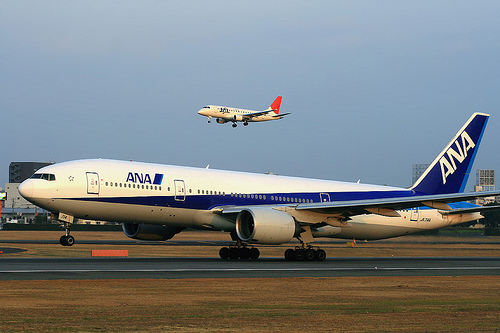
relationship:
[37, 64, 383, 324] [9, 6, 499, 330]
planes at an airport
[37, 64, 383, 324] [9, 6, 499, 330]
two planes at an airport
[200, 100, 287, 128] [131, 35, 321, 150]
plane in air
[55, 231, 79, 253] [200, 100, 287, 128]
front tires on plane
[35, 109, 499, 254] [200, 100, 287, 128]
white and blue plane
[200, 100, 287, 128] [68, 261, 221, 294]
plane on runway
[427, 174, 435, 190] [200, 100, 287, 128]
blue and white plane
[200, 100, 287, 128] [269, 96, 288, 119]
plane has orange tail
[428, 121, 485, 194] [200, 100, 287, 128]
ana on plane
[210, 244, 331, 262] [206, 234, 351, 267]
black plane tires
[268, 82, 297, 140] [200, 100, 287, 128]
red tail end of plane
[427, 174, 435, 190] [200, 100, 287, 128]
blue end of plane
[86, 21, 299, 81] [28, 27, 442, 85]
clear blue sky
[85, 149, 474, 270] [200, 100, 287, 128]
right side of plane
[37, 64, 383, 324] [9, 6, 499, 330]
planes are in airport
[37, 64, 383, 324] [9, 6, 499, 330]
planes in an airport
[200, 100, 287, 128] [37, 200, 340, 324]
plane taking off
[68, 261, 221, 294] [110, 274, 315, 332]
runway has grass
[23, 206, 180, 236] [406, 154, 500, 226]
buildings in background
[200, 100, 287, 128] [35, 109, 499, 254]
plane red and white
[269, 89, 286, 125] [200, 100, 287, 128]
red and white plane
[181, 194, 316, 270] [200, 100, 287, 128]
engines on plane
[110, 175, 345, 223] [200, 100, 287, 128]
windows on plane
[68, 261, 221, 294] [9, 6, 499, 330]
runway of an airport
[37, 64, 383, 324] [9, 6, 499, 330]
planes in airport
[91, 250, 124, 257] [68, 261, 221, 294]
orange barrier next to runway